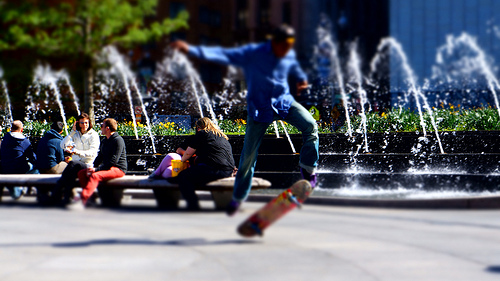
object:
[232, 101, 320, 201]
pants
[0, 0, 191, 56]
leaves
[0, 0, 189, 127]
tree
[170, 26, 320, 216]
skateboarder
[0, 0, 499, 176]
air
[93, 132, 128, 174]
top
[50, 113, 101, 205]
woman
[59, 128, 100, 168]
jacket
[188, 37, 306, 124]
shirt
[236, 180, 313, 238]
skateboard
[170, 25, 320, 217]
boy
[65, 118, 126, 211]
man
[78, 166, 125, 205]
pants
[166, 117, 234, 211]
woman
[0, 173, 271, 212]
bench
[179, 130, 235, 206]
outfit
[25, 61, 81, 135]
fountain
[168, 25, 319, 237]
skate boarder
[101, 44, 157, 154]
fountain